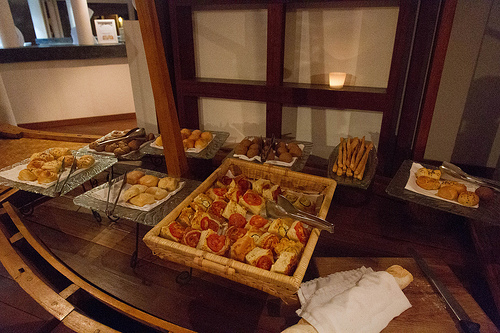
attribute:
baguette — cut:
[124, 168, 180, 210]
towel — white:
[299, 255, 413, 331]